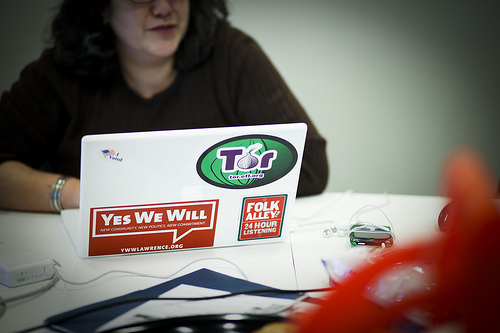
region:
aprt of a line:
[181, 216, 218, 254]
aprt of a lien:
[162, 183, 199, 230]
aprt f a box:
[147, 162, 165, 194]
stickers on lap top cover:
[82, 123, 299, 256]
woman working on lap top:
[19, 0, 344, 250]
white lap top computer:
[69, 114, 302, 246]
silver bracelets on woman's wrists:
[38, 161, 71, 224]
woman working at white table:
[5, 182, 488, 328]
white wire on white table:
[54, 250, 254, 294]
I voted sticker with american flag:
[95, 143, 131, 172]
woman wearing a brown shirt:
[22, 0, 352, 200]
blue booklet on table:
[43, 261, 317, 330]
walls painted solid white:
[376, 28, 453, 165]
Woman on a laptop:
[58, 122, 311, 262]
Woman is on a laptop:
[54, 117, 311, 262]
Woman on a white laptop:
[59, 114, 309, 260]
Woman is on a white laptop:
[58, 116, 310, 261]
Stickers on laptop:
[88, 132, 296, 258]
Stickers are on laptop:
[86, 127, 296, 261]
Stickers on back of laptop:
[85, 131, 298, 259]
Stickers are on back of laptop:
[83, 129, 299, 259]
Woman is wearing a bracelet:
[48, 170, 74, 212]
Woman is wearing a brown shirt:
[0, 12, 343, 204]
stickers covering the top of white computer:
[66, 121, 299, 267]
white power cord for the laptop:
[5, 238, 260, 321]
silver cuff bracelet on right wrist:
[32, 166, 91, 224]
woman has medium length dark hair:
[41, 2, 247, 92]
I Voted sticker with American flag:
[92, 146, 142, 171]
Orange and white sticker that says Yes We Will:
[83, 186, 221, 263]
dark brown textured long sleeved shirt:
[4, 41, 336, 233]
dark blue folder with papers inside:
[34, 265, 279, 331]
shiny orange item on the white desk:
[298, 156, 489, 322]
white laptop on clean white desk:
[36, 115, 312, 277]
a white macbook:
[59, 99, 403, 289]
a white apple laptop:
[36, 87, 374, 279]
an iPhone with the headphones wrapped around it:
[329, 197, 400, 257]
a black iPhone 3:
[344, 234, 405, 254]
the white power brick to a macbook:
[3, 249, 81, 314]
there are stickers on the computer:
[62, 110, 355, 255]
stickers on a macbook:
[73, 120, 317, 275]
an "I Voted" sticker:
[90, 136, 133, 170]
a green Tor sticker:
[190, 129, 324, 196]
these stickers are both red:
[83, 195, 308, 254]